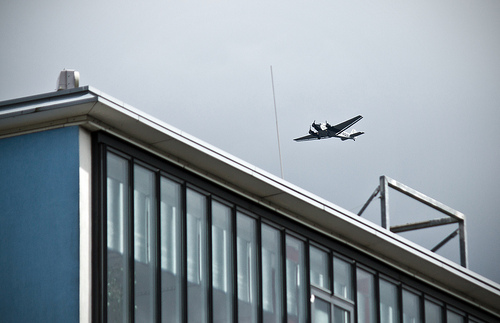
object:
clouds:
[136, 23, 393, 95]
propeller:
[306, 117, 318, 129]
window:
[161, 177, 185, 322]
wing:
[288, 132, 311, 143]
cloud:
[6, 4, 498, 274]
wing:
[331, 112, 364, 132]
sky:
[1, 1, 499, 272]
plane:
[293, 112, 366, 142]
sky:
[14, 1, 474, 291]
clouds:
[135, 18, 247, 81]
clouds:
[181, 17, 262, 67]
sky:
[294, 6, 411, 58]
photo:
[3, 4, 498, 318]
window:
[172, 194, 196, 297]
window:
[131, 162, 162, 321]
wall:
[3, 84, 120, 321]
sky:
[204, 22, 463, 60]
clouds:
[255, 52, 372, 104]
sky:
[25, 19, 475, 232]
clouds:
[300, 4, 499, 112]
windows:
[132, 161, 157, 321]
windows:
[185, 185, 208, 320]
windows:
[236, 210, 257, 320]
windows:
[310, 244, 331, 291]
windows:
[356, 265, 376, 320]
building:
[115, 180, 326, 320]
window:
[229, 178, 283, 316]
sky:
[0, 2, 497, 232]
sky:
[6, 5, 498, 119]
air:
[175, 75, 359, 120]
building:
[7, 63, 497, 322]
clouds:
[334, 25, 433, 94]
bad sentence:
[204, 86, 224, 109]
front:
[306, 115, 327, 135]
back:
[337, 128, 367, 146]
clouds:
[295, 23, 427, 83]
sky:
[2, 3, 498, 210]